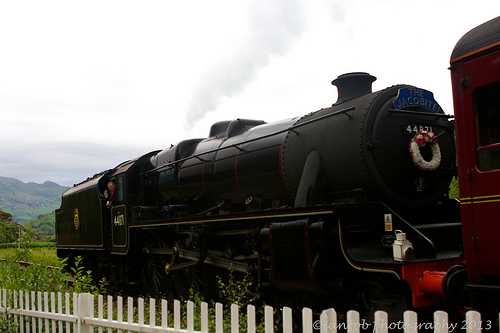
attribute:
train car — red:
[426, 28, 495, 295]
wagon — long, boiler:
[49, 67, 438, 329]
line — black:
[81, 220, 356, 305]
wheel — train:
[266, 242, 348, 299]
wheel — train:
[149, 240, 214, 291]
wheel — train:
[99, 242, 164, 290]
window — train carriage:
[468, 73, 498, 173]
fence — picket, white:
[3, 276, 199, 331]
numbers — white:
[404, 114, 439, 139]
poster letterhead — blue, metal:
[384, 85, 448, 117]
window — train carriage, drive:
[104, 164, 123, 221]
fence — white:
[1, 289, 482, 331]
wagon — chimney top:
[47, 69, 459, 305]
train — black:
[48, 63, 460, 297]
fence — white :
[90, 270, 173, 327]